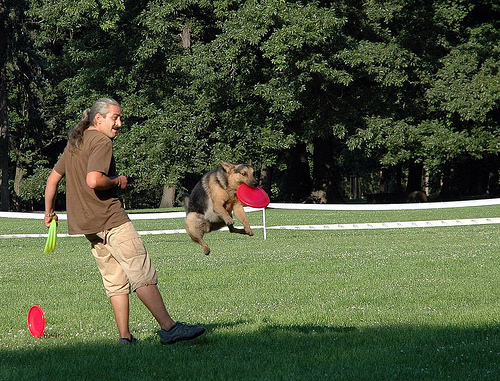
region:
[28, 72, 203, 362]
A man holding a frisbee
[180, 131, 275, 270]
A dog with a frisbee in his mouth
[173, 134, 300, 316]
A dog in the air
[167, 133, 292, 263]
A dog in the air with a frisbee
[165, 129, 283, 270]
A dog with a red frisbee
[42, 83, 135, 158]
A man with a pony tail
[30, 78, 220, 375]
A man with a brown shirt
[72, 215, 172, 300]
A man with tan shorts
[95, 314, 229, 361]
A man wearing tennis shoes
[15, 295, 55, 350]
A red frisbee on the ground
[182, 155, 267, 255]
Dog jumping air catching a frisbee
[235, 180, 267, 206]
Red plastic frisbee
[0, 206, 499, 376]
well groomed grassy field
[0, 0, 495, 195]
tall green trees providing shade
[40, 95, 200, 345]
Man playing with dog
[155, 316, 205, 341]
gray tennis shoe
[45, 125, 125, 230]
comfortable brown t-shirt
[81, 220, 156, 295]
tan cargo shorts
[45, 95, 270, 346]
Training a dog to catch a frisbee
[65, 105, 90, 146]
Long Grey ponytail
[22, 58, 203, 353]
older man standing in the grass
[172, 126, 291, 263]
dog catching a Frisbee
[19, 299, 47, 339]
red Frisbee propped up in the grass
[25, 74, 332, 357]
man playing Frisbee with his dog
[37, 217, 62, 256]
stack of Frisbees in the hand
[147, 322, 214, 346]
foot slightly lifted off the ground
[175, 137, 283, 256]
dog in the air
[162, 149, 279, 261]
brown and black dog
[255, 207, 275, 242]
white pole sticking out of the grass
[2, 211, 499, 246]
walking path running through the grass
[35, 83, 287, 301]
Slow motion well shown.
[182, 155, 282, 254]
German Sheppard air Frisbee.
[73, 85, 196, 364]
Man close to fall over.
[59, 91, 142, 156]
Man ponytail mustache.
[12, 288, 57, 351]
Red Frisbee balanced grass.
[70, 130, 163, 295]
Brown shirt khaki shorts.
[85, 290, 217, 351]
Bare legs sneakers feet.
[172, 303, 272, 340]
Slight shadow from man.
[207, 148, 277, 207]
Ears back tight grip Frisbee.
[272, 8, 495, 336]
Green grass green trees.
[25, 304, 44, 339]
red frisbee rolling on the ground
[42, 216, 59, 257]
stack of yellow frisbees ready to be thrown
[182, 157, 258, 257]
german shepard in mid-air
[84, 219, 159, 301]
khaki cargo shorts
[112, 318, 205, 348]
gray tennis shoes with black soles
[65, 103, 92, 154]
gray, dark brown, and white pony tail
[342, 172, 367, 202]
opening in the trees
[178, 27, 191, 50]
partially shown tree trunk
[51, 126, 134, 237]
brown t-shirt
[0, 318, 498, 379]
shadow along the ground of something we can't see